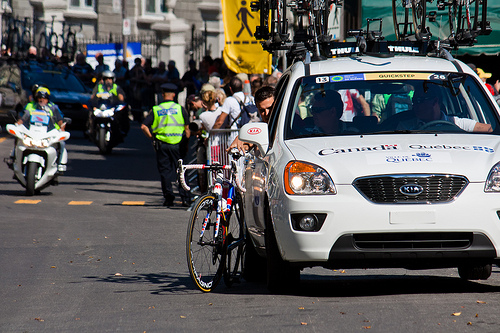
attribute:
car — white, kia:
[235, 53, 497, 282]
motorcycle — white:
[6, 112, 71, 197]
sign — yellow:
[219, 3, 272, 74]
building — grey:
[2, 2, 224, 76]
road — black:
[2, 122, 497, 332]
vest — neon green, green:
[150, 100, 185, 144]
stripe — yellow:
[17, 197, 145, 207]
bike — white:
[179, 157, 244, 291]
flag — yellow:
[221, 1, 271, 75]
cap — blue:
[160, 83, 179, 93]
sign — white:
[88, 43, 141, 72]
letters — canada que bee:
[318, 143, 470, 154]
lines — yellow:
[17, 197, 147, 205]